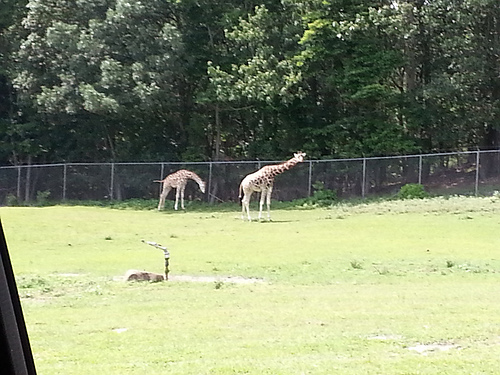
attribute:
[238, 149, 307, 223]
giraffe — looking up, standing, in distance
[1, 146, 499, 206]
fence — chain link, gray, metal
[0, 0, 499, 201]
trees — green, dense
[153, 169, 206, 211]
giraffe — looking down, bent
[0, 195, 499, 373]
grass — green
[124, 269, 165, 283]
rock — flat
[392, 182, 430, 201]
bush — small, green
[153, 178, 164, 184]
tail — sticking out, straight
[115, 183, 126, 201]
tree trunk — bare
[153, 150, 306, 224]
giraffes — standing, spotted, together, orange, brown, fenced in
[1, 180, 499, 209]
shrubs — shaded, growing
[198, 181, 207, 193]
giraffe head — down, bowed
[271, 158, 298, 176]
neck — sticking out, long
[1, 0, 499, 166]
branches — brown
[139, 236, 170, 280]
pipe — metal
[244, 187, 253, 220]
giraffe's leg — long